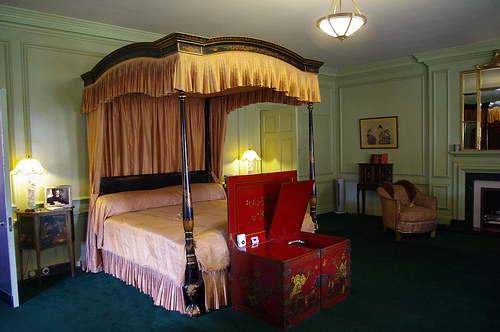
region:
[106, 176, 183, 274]
the bed is pink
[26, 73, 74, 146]
the wall is green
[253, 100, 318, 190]
the door is open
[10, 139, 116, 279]
lamp on the side of the bed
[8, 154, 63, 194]
lamp is turned on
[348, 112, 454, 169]
painting on the wall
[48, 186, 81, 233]
picture frame on the side table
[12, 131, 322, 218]
two lamps on the side of the bed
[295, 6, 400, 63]
the light is turned on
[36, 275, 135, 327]
the carpet is blue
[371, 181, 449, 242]
a pink damask chair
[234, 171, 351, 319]
a red oriental styled chest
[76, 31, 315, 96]
a canopy over a bed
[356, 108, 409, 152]
a framed painting on the wall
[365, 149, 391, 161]
books on side table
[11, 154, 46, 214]
a lamp on a nightstand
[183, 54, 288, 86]
a pink ruffle dangling from the canopy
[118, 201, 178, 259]
a silk pink bedspread on the bed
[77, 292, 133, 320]
blue carpet covering the floor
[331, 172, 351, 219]
a cylindrical heater in the corner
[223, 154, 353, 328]
ornate red trunk at base of bed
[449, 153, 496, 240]
fireplace with white mantle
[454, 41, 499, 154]
ornate gold mirror hung above fireplace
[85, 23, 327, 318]
decorative canopy bed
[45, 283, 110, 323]
teal blue rug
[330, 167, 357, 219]
white air conditioner in corner of room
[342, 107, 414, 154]
oriental painting hung on wall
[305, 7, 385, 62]
gold and white light hung from ceiling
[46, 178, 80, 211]
picture of a person on bedside table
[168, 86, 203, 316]
black and gold bed post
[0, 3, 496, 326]
the room has a canopied four poster bed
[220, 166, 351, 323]
a red chest in a Chinese motif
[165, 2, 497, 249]
a fireplace in a bedroom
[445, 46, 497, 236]
a gilded mirror above the fireplace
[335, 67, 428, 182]
a painting on the bedroom wall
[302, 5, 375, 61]
a light fixture hanging from the ceiling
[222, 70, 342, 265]
the door is open into the bedroom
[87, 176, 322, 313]
a pink ruffled bedspread is on the bed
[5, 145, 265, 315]
a lamp is on each bedside table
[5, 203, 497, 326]
the carpet is blue in the bedroom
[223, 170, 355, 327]
red decorated chest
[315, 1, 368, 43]
gold and white ceiling light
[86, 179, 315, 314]
pink bed spread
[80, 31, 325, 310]
gold bed canope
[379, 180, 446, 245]
upholstered cushioned pink chair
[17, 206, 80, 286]
small wooden end table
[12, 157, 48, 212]
small white end table lamp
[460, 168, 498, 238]
brown and white framed fireplace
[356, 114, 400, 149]
brown frame picture of two people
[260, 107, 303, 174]
green bedroom door